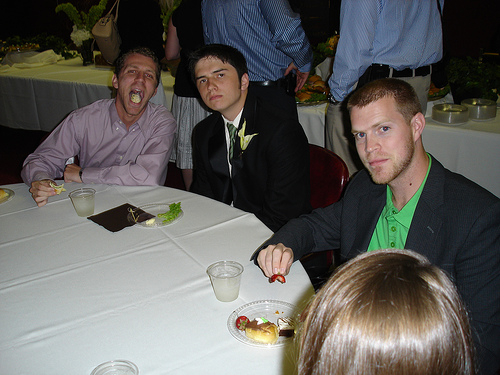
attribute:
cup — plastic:
[187, 252, 256, 308]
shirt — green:
[363, 150, 433, 251]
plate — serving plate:
[217, 280, 294, 355]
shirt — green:
[362, 181, 419, 260]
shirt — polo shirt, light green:
[367, 156, 431, 250]